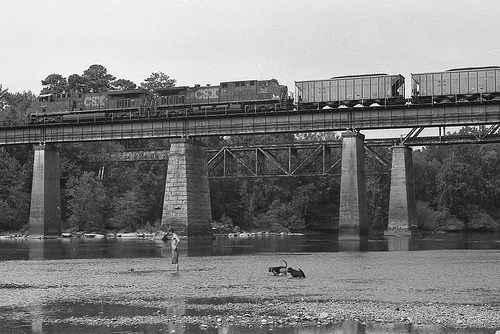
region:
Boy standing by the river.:
[155, 209, 197, 281]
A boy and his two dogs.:
[161, 216, 351, 309]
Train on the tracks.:
[13, 70, 495, 140]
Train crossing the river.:
[5, 5, 390, 259]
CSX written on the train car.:
[156, 74, 298, 119]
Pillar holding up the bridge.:
[125, 108, 255, 275]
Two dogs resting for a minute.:
[255, 242, 335, 312]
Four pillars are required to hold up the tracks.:
[15, 123, 475, 253]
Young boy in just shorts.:
[167, 219, 187, 288]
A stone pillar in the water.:
[155, 138, 221, 252]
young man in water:
[165, 225, 182, 271]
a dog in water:
[265, 258, 290, 280]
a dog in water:
[286, 264, 306, 278]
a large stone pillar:
[159, 138, 212, 232]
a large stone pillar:
[30, 144, 62, 237]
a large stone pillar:
[337, 130, 367, 240]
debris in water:
[2, 251, 498, 332]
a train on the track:
[29, 63, 499, 118]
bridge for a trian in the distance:
[77, 131, 499, 173]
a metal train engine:
[152, 77, 291, 119]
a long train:
[21, 65, 496, 120]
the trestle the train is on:
[0, 100, 495, 240]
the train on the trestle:
[0, 60, 490, 235]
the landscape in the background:
[0, 65, 495, 230]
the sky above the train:
[0, 0, 495, 60]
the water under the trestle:
[0, 230, 495, 255]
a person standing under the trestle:
[165, 225, 180, 275]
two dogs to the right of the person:
[265, 255, 300, 275]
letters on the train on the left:
[80, 90, 100, 100]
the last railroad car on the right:
[410, 65, 496, 100]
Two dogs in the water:
[266, 260, 306, 280]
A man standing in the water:
[168, 225, 182, 273]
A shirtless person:
[170, 225, 180, 247]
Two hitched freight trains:
[123, 89, 192, 106]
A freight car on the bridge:
[313, 85, 378, 97]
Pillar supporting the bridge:
[345, 172, 358, 224]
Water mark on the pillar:
[340, 228, 357, 235]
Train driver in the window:
[40, 95, 45, 102]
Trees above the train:
[66, 78, 115, 87]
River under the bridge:
[293, 239, 328, 248]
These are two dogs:
[213, 219, 347, 329]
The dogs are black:
[262, 255, 319, 280]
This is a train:
[88, 92, 218, 122]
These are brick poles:
[261, 98, 441, 255]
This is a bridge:
[36, 110, 154, 165]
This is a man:
[150, 232, 180, 264]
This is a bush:
[58, 145, 135, 238]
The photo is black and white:
[38, 63, 373, 305]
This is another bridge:
[241, 117, 311, 189]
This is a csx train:
[156, 83, 267, 122]